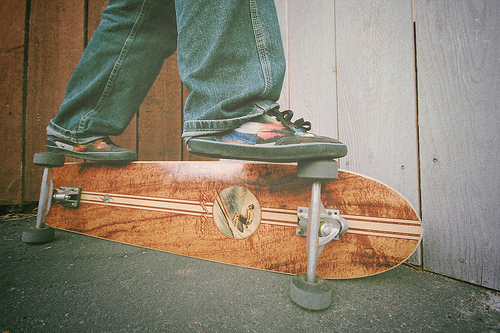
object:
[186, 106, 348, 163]
shoe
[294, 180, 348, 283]
axle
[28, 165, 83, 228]
axle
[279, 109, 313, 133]
shoelace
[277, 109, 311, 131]
lace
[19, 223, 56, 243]
wheel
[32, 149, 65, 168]
wheel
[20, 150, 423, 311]
board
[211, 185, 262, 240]
surf picture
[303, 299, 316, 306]
part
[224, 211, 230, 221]
part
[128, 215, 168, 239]
part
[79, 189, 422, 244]
stripe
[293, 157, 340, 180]
wheel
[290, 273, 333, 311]
wheel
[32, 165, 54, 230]
truck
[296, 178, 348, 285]
truck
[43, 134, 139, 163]
shoe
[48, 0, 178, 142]
pant leg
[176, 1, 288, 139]
pant leg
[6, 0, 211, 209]
wall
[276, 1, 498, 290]
wall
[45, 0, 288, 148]
jeans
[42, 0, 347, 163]
man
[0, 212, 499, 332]
pavement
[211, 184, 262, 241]
circle